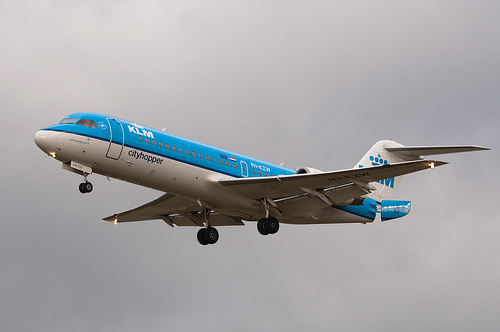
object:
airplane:
[34, 112, 490, 245]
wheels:
[78, 182, 280, 246]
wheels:
[196, 216, 279, 246]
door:
[105, 117, 124, 160]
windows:
[138, 135, 275, 178]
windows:
[57, 118, 98, 129]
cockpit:
[56, 118, 97, 129]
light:
[48, 151, 57, 158]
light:
[112, 217, 118, 226]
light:
[428, 161, 435, 170]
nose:
[34, 123, 66, 154]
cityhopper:
[127, 149, 163, 164]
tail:
[349, 139, 490, 203]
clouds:
[0, 1, 499, 331]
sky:
[0, 0, 499, 331]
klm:
[127, 125, 154, 139]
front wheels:
[78, 182, 93, 194]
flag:
[229, 156, 237, 163]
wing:
[101, 191, 247, 228]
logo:
[358, 153, 397, 189]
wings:
[100, 159, 450, 227]